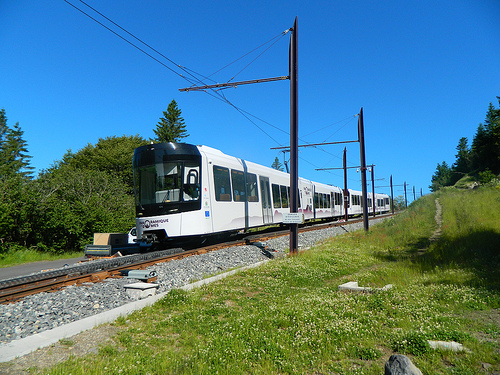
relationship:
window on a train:
[211, 160, 235, 203] [132, 140, 390, 247]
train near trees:
[127, 126, 377, 258] [29, 134, 150, 236]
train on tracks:
[127, 126, 377, 258] [3, 191, 405, 320]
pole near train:
[286, 21, 302, 254] [115, 138, 403, 275]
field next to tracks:
[257, 232, 469, 358] [33, 266, 63, 292]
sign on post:
[271, 210, 305, 228] [281, 12, 301, 254]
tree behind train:
[153, 98, 188, 142] [132, 140, 390, 247]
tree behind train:
[25, 166, 132, 247] [132, 140, 390, 247]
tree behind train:
[54, 136, 146, 183] [132, 140, 390, 247]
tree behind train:
[0, 109, 35, 252] [132, 140, 390, 247]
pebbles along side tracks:
[0, 215, 397, 345] [0, 208, 408, 306]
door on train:
[258, 177, 273, 224] [132, 140, 390, 247]